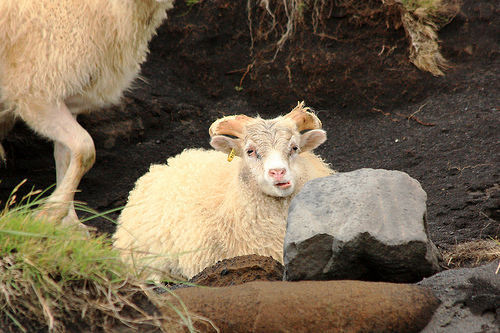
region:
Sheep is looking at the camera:
[101, 97, 331, 278]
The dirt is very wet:
[360, 79, 497, 168]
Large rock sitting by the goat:
[271, 172, 448, 302]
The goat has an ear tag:
[212, 142, 239, 165]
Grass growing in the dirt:
[3, 180, 141, 327]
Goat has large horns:
[202, 107, 257, 129]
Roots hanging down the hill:
[226, 0, 453, 82]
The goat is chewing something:
[257, 141, 297, 188]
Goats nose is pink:
[267, 162, 287, 177]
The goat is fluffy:
[131, 149, 226, 246]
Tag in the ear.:
[215, 140, 242, 170]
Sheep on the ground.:
[109, 92, 368, 261]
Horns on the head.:
[205, 103, 324, 143]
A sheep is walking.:
[0, 0, 163, 235]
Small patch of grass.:
[11, 213, 111, 283]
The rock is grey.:
[291, 172, 443, 277]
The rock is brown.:
[163, 272, 430, 332]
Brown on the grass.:
[11, 278, 145, 330]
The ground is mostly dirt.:
[111, 50, 499, 178]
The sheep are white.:
[3, 5, 329, 275]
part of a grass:
[116, 264, 131, 306]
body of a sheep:
[234, 183, 247, 195]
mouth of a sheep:
[277, 175, 284, 195]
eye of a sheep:
[244, 140, 261, 175]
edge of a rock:
[468, 273, 473, 281]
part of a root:
[415, 115, 432, 150]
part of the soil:
[314, 67, 329, 119]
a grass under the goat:
[3, 179, 124, 307]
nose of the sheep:
[270, 161, 290, 181]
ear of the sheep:
[208, 134, 243, 161]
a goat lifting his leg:
[31, 92, 100, 243]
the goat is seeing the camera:
[189, 101, 347, 231]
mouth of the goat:
[266, 179, 305, 189]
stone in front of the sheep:
[225, 130, 447, 276]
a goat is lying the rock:
[116, 115, 368, 316]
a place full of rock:
[369, 52, 493, 245]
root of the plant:
[246, 16, 410, 86]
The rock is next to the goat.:
[115, 127, 462, 267]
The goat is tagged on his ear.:
[220, 144, 236, 166]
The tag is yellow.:
[222, 141, 239, 162]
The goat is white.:
[109, 105, 344, 276]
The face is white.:
[209, 102, 314, 196]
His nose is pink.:
[265, 164, 282, 180]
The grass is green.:
[8, 188, 157, 318]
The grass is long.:
[7, 193, 191, 323]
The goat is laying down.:
[118, 102, 443, 332]